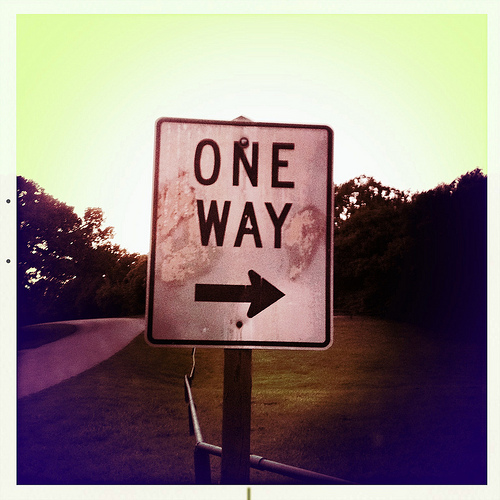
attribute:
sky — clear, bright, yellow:
[17, 15, 491, 289]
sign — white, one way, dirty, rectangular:
[142, 113, 337, 353]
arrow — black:
[192, 268, 287, 319]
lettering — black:
[192, 135, 299, 256]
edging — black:
[140, 113, 338, 355]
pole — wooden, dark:
[217, 348, 255, 483]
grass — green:
[23, 316, 487, 487]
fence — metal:
[183, 346, 357, 484]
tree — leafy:
[18, 172, 89, 323]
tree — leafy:
[95, 283, 137, 317]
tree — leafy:
[336, 169, 410, 237]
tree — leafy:
[336, 198, 402, 320]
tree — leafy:
[404, 165, 486, 329]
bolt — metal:
[233, 319, 247, 330]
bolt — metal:
[239, 135, 252, 150]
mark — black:
[159, 168, 220, 292]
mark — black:
[280, 202, 325, 282]